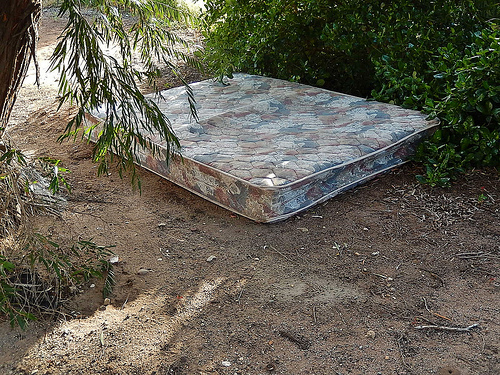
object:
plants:
[398, 13, 486, 90]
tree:
[210, 4, 497, 89]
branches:
[23, 245, 89, 305]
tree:
[0, 0, 46, 152]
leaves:
[203, 0, 500, 183]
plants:
[207, 3, 499, 154]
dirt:
[0, 0, 500, 375]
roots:
[33, 195, 138, 310]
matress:
[77, 66, 449, 219]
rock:
[138, 268, 149, 276]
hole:
[5, 261, 46, 322]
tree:
[284, 2, 497, 99]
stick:
[413, 322, 480, 335]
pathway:
[0, 2, 499, 372]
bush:
[190, 0, 497, 183]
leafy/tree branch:
[45, 2, 253, 183]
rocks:
[206, 255, 219, 264]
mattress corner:
[242, 179, 297, 229]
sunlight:
[42, 30, 194, 85]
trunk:
[1, 0, 41, 138]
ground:
[0, 0, 500, 375]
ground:
[149, 217, 355, 327]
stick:
[392, 321, 412, 369]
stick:
[454, 243, 484, 263]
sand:
[0, 8, 499, 373]